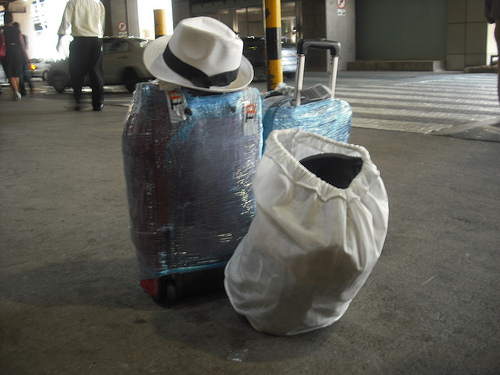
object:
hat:
[139, 15, 254, 96]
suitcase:
[120, 71, 264, 310]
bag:
[222, 126, 389, 338]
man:
[54, 0, 106, 114]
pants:
[65, 36, 106, 112]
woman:
[0, 13, 34, 103]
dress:
[0, 25, 30, 80]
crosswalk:
[301, 66, 499, 136]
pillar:
[258, 0, 284, 92]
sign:
[336, 0, 350, 11]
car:
[45, 36, 157, 95]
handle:
[290, 36, 342, 109]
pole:
[262, 0, 285, 92]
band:
[160, 44, 238, 91]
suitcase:
[258, 37, 353, 165]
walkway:
[0, 88, 499, 374]